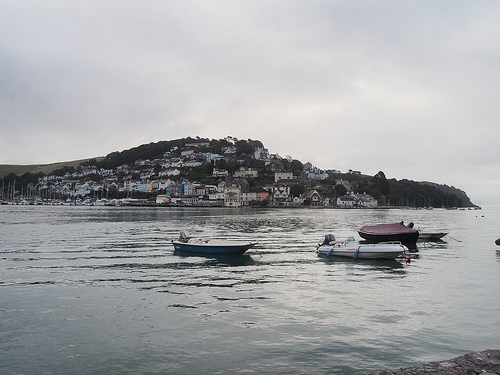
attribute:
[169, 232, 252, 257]
boat — white, blue, floating, on the left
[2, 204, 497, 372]
water — rippled, a harbor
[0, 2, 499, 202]
sky — white, cloudy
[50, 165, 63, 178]
tree — green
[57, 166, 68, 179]
tree — green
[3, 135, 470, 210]
hill — tall, in background, island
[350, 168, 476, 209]
end of hill — houseless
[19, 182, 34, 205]
sailboat — across the way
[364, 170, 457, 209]
forest — green